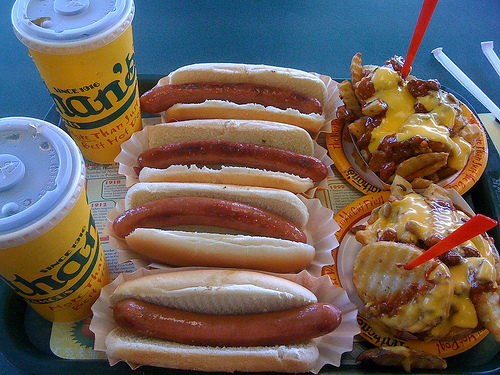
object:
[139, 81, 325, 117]
hot dog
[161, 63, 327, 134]
buns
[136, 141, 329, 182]
hot dog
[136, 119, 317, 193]
buns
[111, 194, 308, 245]
hot dog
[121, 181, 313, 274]
buns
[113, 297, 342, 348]
hot dog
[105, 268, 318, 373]
buns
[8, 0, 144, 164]
cup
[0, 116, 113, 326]
cup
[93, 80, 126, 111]
writing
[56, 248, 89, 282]
writing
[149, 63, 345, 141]
white wrapper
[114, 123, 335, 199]
white wrapper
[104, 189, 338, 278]
white wrapper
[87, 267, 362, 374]
white wrapper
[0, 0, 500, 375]
food and drinks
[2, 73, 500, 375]
tray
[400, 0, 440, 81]
fork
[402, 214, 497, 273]
fork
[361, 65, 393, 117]
chilli fries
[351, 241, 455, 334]
chilli fries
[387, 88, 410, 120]
cheese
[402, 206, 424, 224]
cheese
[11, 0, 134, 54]
lid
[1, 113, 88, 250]
lid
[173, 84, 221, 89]
grill marks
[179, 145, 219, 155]
grill marks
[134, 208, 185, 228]
grill marks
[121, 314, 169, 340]
grill marks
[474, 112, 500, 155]
straw wrappers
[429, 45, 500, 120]
straw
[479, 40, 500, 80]
straw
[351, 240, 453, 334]
potato slice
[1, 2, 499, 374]
table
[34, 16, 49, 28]
soda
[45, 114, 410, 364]
paper menu